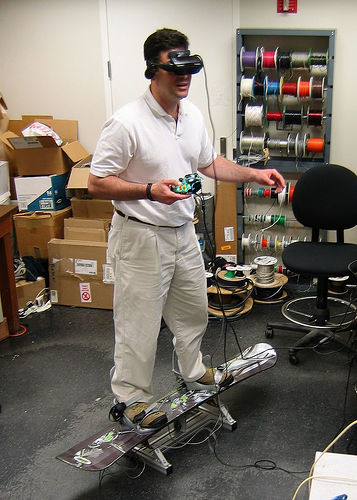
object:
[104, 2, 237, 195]
door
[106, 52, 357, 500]
cables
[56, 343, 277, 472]
skateboard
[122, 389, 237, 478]
frame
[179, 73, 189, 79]
nose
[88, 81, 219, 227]
white shirt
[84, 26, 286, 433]
man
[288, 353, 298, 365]
wheels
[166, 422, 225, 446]
wire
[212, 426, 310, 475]
wire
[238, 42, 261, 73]
rolls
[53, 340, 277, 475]
snowboarding game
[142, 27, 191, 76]
hair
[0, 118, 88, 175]
boxes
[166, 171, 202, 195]
game controller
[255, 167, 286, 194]
hand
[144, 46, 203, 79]
face gear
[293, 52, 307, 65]
spool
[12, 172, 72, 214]
box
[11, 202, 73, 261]
box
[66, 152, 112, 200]
box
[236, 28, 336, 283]
cabinet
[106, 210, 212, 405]
pants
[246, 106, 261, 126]
spool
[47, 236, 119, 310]
box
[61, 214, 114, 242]
box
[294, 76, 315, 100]
spool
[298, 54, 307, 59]
wire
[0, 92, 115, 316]
collection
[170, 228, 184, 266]
zipper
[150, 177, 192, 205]
hand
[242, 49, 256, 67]
spool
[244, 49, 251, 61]
wire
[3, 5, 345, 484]
office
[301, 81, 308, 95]
wire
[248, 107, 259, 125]
wire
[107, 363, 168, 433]
gadget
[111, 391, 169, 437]
feet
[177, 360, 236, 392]
feet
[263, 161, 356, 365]
chair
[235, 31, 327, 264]
cables